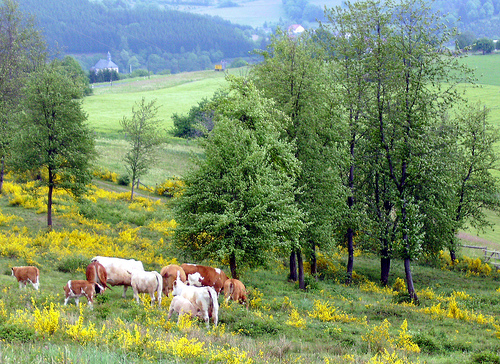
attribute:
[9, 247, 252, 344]
cows — white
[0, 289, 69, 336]
flowers — yellow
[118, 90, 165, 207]
tree — green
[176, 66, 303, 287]
tree — green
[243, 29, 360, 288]
tree — green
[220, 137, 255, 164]
leaves — green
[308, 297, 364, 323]
flowers — yellow, wild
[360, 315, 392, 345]
flowers — yellow, wild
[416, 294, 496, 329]
flowers — yellow, wild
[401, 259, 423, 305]
tree — brown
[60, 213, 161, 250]
flowers — yellow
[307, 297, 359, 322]
flowers — yellow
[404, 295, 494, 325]
flowers — yellow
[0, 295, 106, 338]
flowers — yellow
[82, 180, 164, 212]
flowers — yellow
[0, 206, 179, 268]
flowers — yellow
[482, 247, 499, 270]
gate — metal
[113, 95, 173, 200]
tree — skinny, green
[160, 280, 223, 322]
cow — small, brown, white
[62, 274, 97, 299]
cow — small, brown, white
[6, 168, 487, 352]
field — flowered, yellow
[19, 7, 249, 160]
hillside — tree covered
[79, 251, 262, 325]
cows — grazing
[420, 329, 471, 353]
grass — green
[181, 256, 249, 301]
cow — dark brown